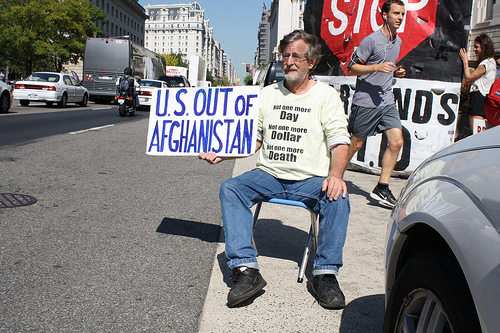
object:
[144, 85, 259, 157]
sign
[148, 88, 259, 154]
letters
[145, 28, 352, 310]
protest